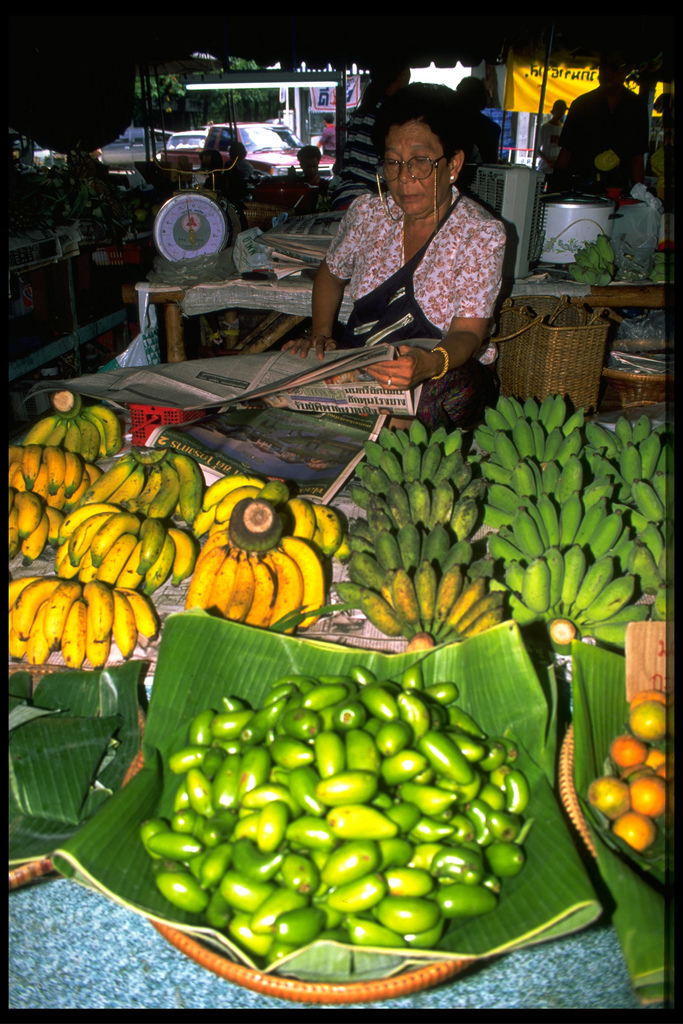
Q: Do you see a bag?
A: Yes, there is a bag.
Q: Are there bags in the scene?
A: Yes, there is a bag.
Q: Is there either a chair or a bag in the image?
A: Yes, there is a bag.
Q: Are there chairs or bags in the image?
A: Yes, there is a bag.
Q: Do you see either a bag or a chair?
A: Yes, there is a bag.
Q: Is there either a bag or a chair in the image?
A: Yes, there is a bag.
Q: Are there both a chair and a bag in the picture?
A: No, there is a bag but no chairs.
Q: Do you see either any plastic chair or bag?
A: Yes, there is a plastic bag.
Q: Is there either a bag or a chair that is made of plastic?
A: Yes, the bag is made of plastic.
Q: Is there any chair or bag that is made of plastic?
A: Yes, the bag is made of plastic.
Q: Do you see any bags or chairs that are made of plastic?
A: Yes, the bag is made of plastic.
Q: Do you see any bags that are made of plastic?
A: Yes, there is a bag that is made of plastic.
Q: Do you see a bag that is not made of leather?
A: Yes, there is a bag that is made of plastic.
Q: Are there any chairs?
A: No, there are no chairs.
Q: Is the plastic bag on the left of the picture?
A: Yes, the bag is on the left of the image.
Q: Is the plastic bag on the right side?
A: No, the bag is on the left of the image.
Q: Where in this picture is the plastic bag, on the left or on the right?
A: The bag is on the left of the image.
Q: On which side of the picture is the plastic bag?
A: The bag is on the left of the image.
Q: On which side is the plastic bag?
A: The bag is on the left of the image.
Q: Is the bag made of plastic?
A: Yes, the bag is made of plastic.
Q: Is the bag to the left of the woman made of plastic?
A: Yes, the bag is made of plastic.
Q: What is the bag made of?
A: The bag is made of plastic.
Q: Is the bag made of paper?
A: No, the bag is made of plastic.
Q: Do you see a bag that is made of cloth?
A: No, there is a bag but it is made of plastic.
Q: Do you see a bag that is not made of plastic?
A: No, there is a bag but it is made of plastic.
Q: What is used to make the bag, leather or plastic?
A: The bag is made of plastic.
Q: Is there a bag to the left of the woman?
A: Yes, there is a bag to the left of the woman.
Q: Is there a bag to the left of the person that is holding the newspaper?
A: Yes, there is a bag to the left of the woman.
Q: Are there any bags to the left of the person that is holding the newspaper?
A: Yes, there is a bag to the left of the woman.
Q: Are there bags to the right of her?
A: No, the bag is to the left of the woman.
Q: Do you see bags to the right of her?
A: No, the bag is to the left of the woman.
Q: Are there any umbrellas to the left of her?
A: No, there is a bag to the left of the woman.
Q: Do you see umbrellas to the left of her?
A: No, there is a bag to the left of the woman.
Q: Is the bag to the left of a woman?
A: Yes, the bag is to the left of a woman.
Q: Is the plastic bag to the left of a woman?
A: Yes, the bag is to the left of a woman.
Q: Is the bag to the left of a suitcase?
A: No, the bag is to the left of a woman.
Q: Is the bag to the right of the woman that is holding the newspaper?
A: No, the bag is to the left of the woman.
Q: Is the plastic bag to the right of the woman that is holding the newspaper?
A: No, the bag is to the left of the woman.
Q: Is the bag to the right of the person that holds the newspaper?
A: No, the bag is to the left of the woman.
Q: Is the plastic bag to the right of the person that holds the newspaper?
A: No, the bag is to the left of the woman.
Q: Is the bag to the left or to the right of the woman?
A: The bag is to the left of the woman.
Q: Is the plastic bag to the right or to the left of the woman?
A: The bag is to the left of the woman.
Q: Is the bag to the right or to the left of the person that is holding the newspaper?
A: The bag is to the left of the woman.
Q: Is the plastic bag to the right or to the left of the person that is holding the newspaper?
A: The bag is to the left of the woman.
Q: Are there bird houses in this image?
A: No, there are no bird houses.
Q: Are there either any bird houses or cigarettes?
A: No, there are no bird houses or cigarettes.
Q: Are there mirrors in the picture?
A: No, there are no mirrors.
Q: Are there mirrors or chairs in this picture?
A: No, there are no mirrors or chairs.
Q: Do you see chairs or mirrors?
A: No, there are no mirrors or chairs.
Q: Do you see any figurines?
A: No, there are no figurines.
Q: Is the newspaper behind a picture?
A: Yes, the newspaper is behind a picture.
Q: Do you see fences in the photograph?
A: No, there are no fences.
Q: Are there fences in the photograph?
A: No, there are no fences.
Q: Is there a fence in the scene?
A: No, there are no fences.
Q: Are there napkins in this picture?
A: No, there are no napkins.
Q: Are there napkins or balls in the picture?
A: No, there are no napkins or balls.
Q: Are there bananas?
A: Yes, there is a banana.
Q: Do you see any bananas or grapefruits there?
A: Yes, there is a banana.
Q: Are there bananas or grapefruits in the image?
A: Yes, there is a banana.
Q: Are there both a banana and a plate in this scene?
A: No, there is a banana but no plates.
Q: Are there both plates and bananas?
A: No, there is a banana but no plates.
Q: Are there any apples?
A: No, there are no apples.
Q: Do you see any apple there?
A: No, there are no apples.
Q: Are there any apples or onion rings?
A: No, there are no apples or onion rings.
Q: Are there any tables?
A: Yes, there is a table.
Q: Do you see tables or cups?
A: Yes, there is a table.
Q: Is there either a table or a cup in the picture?
A: Yes, there is a table.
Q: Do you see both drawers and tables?
A: No, there is a table but no drawers.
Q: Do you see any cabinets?
A: No, there are no cabinets.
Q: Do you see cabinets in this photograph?
A: No, there are no cabinets.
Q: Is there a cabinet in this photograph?
A: No, there are no cabinets.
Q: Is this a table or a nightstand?
A: This is a table.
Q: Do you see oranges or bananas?
A: Yes, there are bananas.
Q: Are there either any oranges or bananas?
A: Yes, there are bananas.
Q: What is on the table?
A: The bananas are on the table.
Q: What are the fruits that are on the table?
A: The fruits are bananas.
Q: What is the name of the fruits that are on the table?
A: The fruits are bananas.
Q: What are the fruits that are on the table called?
A: The fruits are bananas.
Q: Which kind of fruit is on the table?
A: The fruits are bananas.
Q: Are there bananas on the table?
A: Yes, there are bananas on the table.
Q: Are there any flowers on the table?
A: No, there are bananas on the table.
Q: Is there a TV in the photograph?
A: No, there are no televisions.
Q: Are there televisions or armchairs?
A: No, there are no televisions or armchairs.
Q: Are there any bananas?
A: Yes, there are bananas.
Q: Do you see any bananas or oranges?
A: Yes, there are bananas.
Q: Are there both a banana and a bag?
A: Yes, there are both a banana and a bag.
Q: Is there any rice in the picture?
A: No, there is no rice.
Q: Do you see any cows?
A: No, there are no cows.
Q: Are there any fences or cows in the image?
A: No, there are no cows or fences.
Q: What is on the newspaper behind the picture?
A: The tag is on the newspaper.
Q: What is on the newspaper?
A: The tag is on the newspaper.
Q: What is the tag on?
A: The tag is on the newspaper.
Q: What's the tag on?
A: The tag is on the newspaper.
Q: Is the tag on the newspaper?
A: Yes, the tag is on the newspaper.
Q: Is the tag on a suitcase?
A: No, the tag is on the newspaper.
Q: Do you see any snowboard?
A: No, there are no snowboards.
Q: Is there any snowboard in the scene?
A: No, there are no snowboards.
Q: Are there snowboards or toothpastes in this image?
A: No, there are no snowboards or toothpastes.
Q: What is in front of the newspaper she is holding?
A: The picture is in front of the newspaper.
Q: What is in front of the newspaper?
A: The picture is in front of the newspaper.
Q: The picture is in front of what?
A: The picture is in front of the newspaper.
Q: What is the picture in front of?
A: The picture is in front of the newspaper.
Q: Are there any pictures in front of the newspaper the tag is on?
A: Yes, there is a picture in front of the newspaper.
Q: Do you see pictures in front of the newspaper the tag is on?
A: Yes, there is a picture in front of the newspaper.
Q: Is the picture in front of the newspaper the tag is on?
A: Yes, the picture is in front of the newspaper.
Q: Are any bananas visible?
A: Yes, there are bananas.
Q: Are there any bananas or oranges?
A: Yes, there are bananas.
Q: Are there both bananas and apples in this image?
A: No, there are bananas but no apples.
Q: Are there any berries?
A: No, there are no berries.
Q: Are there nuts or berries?
A: No, there are no berries or nuts.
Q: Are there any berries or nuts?
A: No, there are no berries or nuts.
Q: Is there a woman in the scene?
A: Yes, there is a woman.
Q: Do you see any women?
A: Yes, there is a woman.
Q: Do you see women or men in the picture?
A: Yes, there is a woman.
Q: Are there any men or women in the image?
A: Yes, there is a woman.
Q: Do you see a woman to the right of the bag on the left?
A: Yes, there is a woman to the right of the bag.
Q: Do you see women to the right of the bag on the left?
A: Yes, there is a woman to the right of the bag.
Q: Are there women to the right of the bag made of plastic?
A: Yes, there is a woman to the right of the bag.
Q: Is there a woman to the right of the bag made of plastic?
A: Yes, there is a woman to the right of the bag.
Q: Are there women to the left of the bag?
A: No, the woman is to the right of the bag.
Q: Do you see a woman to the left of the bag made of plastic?
A: No, the woman is to the right of the bag.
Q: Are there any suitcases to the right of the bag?
A: No, there is a woman to the right of the bag.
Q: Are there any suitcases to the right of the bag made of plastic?
A: No, there is a woman to the right of the bag.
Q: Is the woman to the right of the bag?
A: Yes, the woman is to the right of the bag.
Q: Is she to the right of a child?
A: No, the woman is to the right of the bag.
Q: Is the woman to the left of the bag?
A: No, the woman is to the right of the bag.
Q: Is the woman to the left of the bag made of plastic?
A: No, the woman is to the right of the bag.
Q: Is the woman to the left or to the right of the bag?
A: The woman is to the right of the bag.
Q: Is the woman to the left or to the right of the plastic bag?
A: The woman is to the right of the bag.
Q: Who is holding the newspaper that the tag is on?
A: The woman is holding the newspaper.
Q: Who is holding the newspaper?
A: The woman is holding the newspaper.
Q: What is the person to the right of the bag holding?
A: The woman is holding the newspaper.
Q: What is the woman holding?
A: The woman is holding the newspaper.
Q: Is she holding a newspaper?
A: Yes, the woman is holding a newspaper.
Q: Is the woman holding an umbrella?
A: No, the woman is holding a newspaper.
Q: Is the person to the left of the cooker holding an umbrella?
A: No, the woman is holding a newspaper.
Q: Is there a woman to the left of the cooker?
A: Yes, there is a woman to the left of the cooker.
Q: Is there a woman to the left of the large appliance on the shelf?
A: Yes, there is a woman to the left of the cooker.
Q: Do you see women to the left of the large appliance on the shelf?
A: Yes, there is a woman to the left of the cooker.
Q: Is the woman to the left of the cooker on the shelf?
A: Yes, the woman is to the left of the cooker.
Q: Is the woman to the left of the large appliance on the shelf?
A: Yes, the woman is to the left of the cooker.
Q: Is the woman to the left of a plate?
A: No, the woman is to the left of the cooker.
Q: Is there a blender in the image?
A: No, there are no blenders.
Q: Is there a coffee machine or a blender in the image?
A: No, there are no blenders or coffee makers.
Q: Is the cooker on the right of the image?
A: Yes, the cooker is on the right of the image.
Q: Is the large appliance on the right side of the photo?
A: Yes, the cooker is on the right of the image.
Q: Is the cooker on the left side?
A: No, the cooker is on the right of the image.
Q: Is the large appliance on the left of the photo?
A: No, the cooker is on the right of the image.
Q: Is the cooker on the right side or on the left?
A: The cooker is on the right of the image.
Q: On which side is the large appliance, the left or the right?
A: The cooker is on the right of the image.